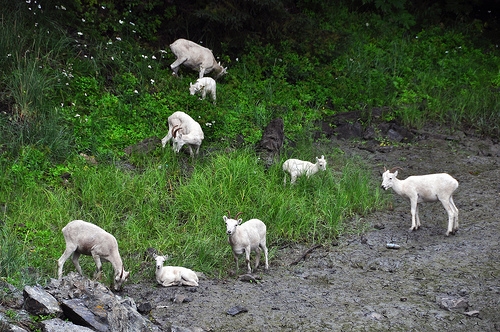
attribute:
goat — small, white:
[279, 151, 334, 187]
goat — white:
[166, 39, 230, 80]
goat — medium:
[275, 151, 331, 183]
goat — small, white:
[378, 166, 466, 238]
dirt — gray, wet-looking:
[302, 245, 434, 320]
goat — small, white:
[374, 162, 461, 237]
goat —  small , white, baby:
[220, 213, 270, 270]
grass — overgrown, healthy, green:
[2, 145, 380, 297]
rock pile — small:
[18, 268, 158, 329]